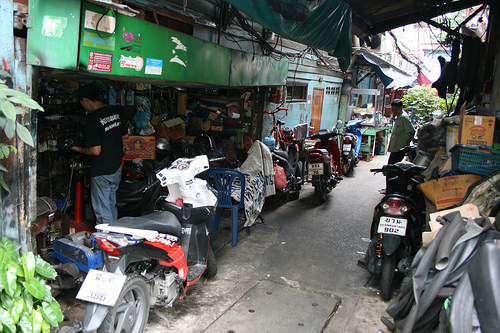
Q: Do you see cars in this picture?
A: No, there are no cars.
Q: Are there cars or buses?
A: No, there are no cars or buses.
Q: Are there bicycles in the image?
A: Yes, there is a bicycle.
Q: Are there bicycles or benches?
A: Yes, there is a bicycle.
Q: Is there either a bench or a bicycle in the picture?
A: Yes, there is a bicycle.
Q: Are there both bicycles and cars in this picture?
A: No, there is a bicycle but no cars.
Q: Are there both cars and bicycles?
A: No, there is a bicycle but no cars.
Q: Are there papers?
A: No, there are no papers.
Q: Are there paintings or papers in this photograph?
A: No, there are no papers or paintings.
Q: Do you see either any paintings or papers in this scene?
A: No, there are no papers or paintings.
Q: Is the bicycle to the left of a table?
A: Yes, the bicycle is to the left of a table.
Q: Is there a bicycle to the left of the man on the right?
A: Yes, there is a bicycle to the left of the man.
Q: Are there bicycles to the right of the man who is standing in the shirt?
A: No, the bicycle is to the left of the man.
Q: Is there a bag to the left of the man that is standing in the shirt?
A: No, there is a bicycle to the left of the man.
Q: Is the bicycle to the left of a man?
A: Yes, the bicycle is to the left of a man.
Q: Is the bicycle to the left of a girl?
A: No, the bicycle is to the left of a man.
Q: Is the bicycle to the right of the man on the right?
A: No, the bicycle is to the left of the man.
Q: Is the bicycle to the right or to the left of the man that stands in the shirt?
A: The bicycle is to the left of the man.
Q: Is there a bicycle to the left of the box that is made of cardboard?
A: Yes, there is a bicycle to the left of the box.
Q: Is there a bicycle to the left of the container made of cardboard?
A: Yes, there is a bicycle to the left of the box.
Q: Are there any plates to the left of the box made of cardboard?
A: No, there is a bicycle to the left of the box.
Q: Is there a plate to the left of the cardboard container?
A: No, there is a bicycle to the left of the box.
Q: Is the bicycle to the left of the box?
A: Yes, the bicycle is to the left of the box.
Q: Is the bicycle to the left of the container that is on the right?
A: Yes, the bicycle is to the left of the box.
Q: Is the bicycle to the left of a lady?
A: No, the bicycle is to the left of the box.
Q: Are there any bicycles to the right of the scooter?
A: Yes, there is a bicycle to the right of the scooter.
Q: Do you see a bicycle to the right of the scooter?
A: Yes, there is a bicycle to the right of the scooter.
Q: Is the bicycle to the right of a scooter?
A: Yes, the bicycle is to the right of a scooter.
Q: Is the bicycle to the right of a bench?
A: No, the bicycle is to the right of a scooter.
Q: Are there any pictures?
A: No, there are no pictures.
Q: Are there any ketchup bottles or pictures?
A: No, there are no pictures or ketchup bottles.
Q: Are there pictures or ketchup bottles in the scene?
A: No, there are no pictures or ketchup bottles.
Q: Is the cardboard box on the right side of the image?
A: Yes, the box is on the right of the image.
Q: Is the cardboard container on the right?
A: Yes, the box is on the right of the image.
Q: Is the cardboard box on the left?
A: No, the box is on the right of the image.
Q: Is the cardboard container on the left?
A: No, the box is on the right of the image.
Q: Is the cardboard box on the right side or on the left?
A: The box is on the right of the image.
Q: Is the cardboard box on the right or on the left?
A: The box is on the right of the image.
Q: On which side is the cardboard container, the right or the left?
A: The box is on the right of the image.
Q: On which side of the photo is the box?
A: The box is on the right of the image.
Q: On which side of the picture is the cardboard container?
A: The box is on the right of the image.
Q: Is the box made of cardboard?
A: Yes, the box is made of cardboard.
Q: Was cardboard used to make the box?
A: Yes, the box is made of cardboard.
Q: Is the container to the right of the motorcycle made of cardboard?
A: Yes, the box is made of cardboard.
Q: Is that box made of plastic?
A: No, the box is made of cardboard.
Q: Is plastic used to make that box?
A: No, the box is made of cardboard.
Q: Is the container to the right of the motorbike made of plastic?
A: No, the box is made of cardboard.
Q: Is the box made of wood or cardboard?
A: The box is made of cardboard.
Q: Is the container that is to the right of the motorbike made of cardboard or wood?
A: The box is made of cardboard.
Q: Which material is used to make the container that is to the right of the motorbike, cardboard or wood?
A: The box is made of cardboard.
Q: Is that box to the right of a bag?
A: No, the box is to the right of the motorbike.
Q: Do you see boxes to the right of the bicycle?
A: Yes, there is a box to the right of the bicycle.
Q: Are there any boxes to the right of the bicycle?
A: Yes, there is a box to the right of the bicycle.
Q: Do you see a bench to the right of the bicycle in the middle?
A: No, there is a box to the right of the bicycle.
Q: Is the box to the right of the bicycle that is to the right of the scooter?
A: Yes, the box is to the right of the bicycle.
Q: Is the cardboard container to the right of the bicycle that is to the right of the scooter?
A: Yes, the box is to the right of the bicycle.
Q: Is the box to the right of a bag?
A: No, the box is to the right of the bicycle.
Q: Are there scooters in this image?
A: Yes, there is a scooter.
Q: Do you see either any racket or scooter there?
A: Yes, there is a scooter.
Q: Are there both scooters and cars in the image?
A: No, there is a scooter but no cars.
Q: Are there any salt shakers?
A: No, there are no salt shakers.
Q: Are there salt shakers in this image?
A: No, there are no salt shakers.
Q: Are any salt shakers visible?
A: No, there are no salt shakers.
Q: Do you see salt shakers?
A: No, there are no salt shakers.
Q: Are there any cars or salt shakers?
A: No, there are no salt shakers or cars.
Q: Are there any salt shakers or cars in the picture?
A: No, there are no salt shakers or cars.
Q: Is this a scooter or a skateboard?
A: This is a scooter.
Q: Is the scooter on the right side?
A: No, the scooter is on the left of the image.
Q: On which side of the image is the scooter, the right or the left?
A: The scooter is on the left of the image.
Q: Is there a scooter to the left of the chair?
A: Yes, there is a scooter to the left of the chair.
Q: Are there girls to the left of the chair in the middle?
A: No, there is a scooter to the left of the chair.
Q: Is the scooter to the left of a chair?
A: Yes, the scooter is to the left of a chair.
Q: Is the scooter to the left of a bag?
A: No, the scooter is to the left of a chair.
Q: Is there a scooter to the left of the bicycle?
A: Yes, there is a scooter to the left of the bicycle.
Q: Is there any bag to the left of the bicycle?
A: No, there is a scooter to the left of the bicycle.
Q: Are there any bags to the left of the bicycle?
A: No, there is a scooter to the left of the bicycle.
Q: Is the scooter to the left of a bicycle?
A: Yes, the scooter is to the left of a bicycle.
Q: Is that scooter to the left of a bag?
A: No, the scooter is to the left of a bicycle.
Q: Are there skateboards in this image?
A: No, there are no skateboards.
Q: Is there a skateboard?
A: No, there are no skateboards.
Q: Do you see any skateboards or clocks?
A: No, there are no skateboards or clocks.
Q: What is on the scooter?
A: The seat is on the scooter.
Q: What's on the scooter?
A: The seat is on the scooter.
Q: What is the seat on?
A: The seat is on the scooter.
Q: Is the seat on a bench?
A: No, the seat is on the scooter.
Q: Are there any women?
A: No, there are no women.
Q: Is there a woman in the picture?
A: No, there are no women.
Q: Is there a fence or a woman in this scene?
A: No, there are no women or fences.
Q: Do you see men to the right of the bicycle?
A: Yes, there is a man to the right of the bicycle.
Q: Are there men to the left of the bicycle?
A: No, the man is to the right of the bicycle.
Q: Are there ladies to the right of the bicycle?
A: No, there is a man to the right of the bicycle.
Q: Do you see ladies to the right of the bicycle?
A: No, there is a man to the right of the bicycle.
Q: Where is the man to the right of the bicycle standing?
A: The man is standing in the shirt.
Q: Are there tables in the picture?
A: Yes, there is a table.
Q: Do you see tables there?
A: Yes, there is a table.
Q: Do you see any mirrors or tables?
A: Yes, there is a table.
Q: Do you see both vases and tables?
A: No, there is a table but no vases.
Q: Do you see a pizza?
A: No, there are no pizzas.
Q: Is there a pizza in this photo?
A: No, there are no pizzas.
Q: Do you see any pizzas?
A: No, there are no pizzas.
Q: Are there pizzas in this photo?
A: No, there are no pizzas.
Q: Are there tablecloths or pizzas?
A: No, there are no pizzas or tablecloths.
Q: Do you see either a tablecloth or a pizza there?
A: No, there are no pizzas or tablecloths.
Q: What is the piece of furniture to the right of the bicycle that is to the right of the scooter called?
A: The piece of furniture is a table.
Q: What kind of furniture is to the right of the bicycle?
A: The piece of furniture is a table.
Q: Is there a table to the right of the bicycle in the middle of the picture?
A: Yes, there is a table to the right of the bicycle.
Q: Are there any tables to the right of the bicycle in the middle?
A: Yes, there is a table to the right of the bicycle.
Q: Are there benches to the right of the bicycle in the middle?
A: No, there is a table to the right of the bicycle.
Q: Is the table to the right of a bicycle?
A: Yes, the table is to the right of a bicycle.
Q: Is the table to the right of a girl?
A: No, the table is to the right of a bicycle.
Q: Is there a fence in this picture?
A: No, there are no fences.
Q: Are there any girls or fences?
A: No, there are no fences or girls.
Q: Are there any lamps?
A: No, there are no lamps.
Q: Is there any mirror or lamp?
A: No, there are no lamps or mirrors.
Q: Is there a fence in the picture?
A: No, there are no fences.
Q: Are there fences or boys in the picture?
A: No, there are no fences or boys.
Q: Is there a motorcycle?
A: Yes, there is a motorcycle.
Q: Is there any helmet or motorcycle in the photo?
A: Yes, there is a motorcycle.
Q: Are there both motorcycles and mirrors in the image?
A: No, there is a motorcycle but no mirrors.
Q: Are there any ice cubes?
A: No, there are no ice cubes.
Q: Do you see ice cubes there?
A: No, there are no ice cubes.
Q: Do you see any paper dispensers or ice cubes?
A: No, there are no ice cubes or paper dispensers.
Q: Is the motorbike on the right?
A: Yes, the motorbike is on the right of the image.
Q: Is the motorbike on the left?
A: No, the motorbike is on the right of the image.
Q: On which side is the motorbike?
A: The motorbike is on the right of the image.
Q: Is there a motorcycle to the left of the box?
A: Yes, there is a motorcycle to the left of the box.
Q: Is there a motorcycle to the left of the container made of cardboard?
A: Yes, there is a motorcycle to the left of the box.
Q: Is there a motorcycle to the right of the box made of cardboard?
A: No, the motorcycle is to the left of the box.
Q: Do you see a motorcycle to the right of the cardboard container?
A: No, the motorcycle is to the left of the box.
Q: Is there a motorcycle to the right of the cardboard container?
A: No, the motorcycle is to the left of the box.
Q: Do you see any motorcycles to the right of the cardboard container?
A: No, the motorcycle is to the left of the box.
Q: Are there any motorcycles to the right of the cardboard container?
A: No, the motorcycle is to the left of the box.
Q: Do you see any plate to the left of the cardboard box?
A: No, there is a motorcycle to the left of the box.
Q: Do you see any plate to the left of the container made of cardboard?
A: No, there is a motorcycle to the left of the box.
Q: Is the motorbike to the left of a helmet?
A: No, the motorbike is to the left of the box.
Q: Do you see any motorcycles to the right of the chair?
A: Yes, there is a motorcycle to the right of the chair.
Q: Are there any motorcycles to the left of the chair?
A: No, the motorcycle is to the right of the chair.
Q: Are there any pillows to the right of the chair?
A: No, there is a motorcycle to the right of the chair.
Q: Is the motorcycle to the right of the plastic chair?
A: Yes, the motorcycle is to the right of the chair.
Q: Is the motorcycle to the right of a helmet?
A: No, the motorcycle is to the right of the chair.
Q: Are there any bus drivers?
A: No, there are no bus drivers.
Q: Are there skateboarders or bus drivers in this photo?
A: No, there are no bus drivers or skateboarders.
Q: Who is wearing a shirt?
A: The man is wearing a shirt.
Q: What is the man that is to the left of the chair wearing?
A: The man is wearing a shirt.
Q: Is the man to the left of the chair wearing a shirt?
A: Yes, the man is wearing a shirt.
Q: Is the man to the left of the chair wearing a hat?
A: No, the man is wearing a shirt.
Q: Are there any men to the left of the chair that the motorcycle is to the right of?
A: Yes, there is a man to the left of the chair.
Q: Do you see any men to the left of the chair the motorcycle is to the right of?
A: Yes, there is a man to the left of the chair.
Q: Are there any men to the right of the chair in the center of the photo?
A: No, the man is to the left of the chair.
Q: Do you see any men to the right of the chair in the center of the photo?
A: No, the man is to the left of the chair.